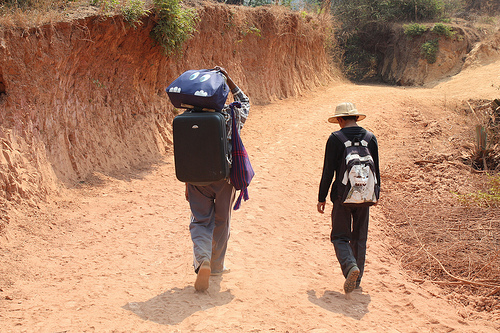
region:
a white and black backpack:
[335, 136, 378, 203]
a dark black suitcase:
[157, 108, 231, 188]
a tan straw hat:
[314, 98, 371, 124]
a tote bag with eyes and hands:
[162, 63, 237, 113]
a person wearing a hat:
[307, 98, 390, 298]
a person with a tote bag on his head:
[148, 56, 259, 299]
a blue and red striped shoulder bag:
[225, 101, 257, 212]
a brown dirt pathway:
[53, 212, 169, 317]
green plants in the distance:
[340, 11, 401, 76]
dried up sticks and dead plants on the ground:
[422, 208, 499, 284]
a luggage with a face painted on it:
[167, 68, 228, 110]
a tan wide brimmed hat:
[327, 101, 365, 122]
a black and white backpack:
[332, 130, 378, 204]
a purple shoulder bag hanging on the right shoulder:
[228, 105, 253, 210]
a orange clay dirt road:
[0, 6, 497, 331]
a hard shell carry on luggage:
[172, 111, 232, 183]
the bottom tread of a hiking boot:
[342, 266, 359, 292]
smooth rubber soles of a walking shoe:
[195, 261, 210, 292]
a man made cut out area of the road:
[1, 0, 330, 204]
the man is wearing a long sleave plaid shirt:
[222, 85, 249, 148]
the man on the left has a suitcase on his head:
[146, 45, 261, 115]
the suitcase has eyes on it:
[163, 53, 258, 128]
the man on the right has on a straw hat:
[298, 88, 363, 130]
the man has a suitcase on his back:
[171, 118, 238, 195]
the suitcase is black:
[171, 110, 243, 197]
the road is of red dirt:
[51, 207, 166, 319]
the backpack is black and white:
[333, 140, 388, 224]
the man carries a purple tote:
[231, 127, 263, 194]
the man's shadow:
[301, 269, 383, 316]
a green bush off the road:
[136, 2, 203, 49]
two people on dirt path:
[149, 56, 373, 298]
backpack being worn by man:
[335, 133, 380, 211]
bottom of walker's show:
[337, 260, 370, 294]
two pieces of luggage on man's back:
[164, 65, 235, 190]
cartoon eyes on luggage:
[182, 69, 216, 88]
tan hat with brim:
[326, 98, 375, 126]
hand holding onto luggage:
[201, 60, 233, 83]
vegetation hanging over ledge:
[150, 9, 193, 60]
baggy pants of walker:
[190, 190, 233, 256]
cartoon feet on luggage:
[166, 86, 213, 102]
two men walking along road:
[151, 56, 416, 304]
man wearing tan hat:
[313, 88, 410, 153]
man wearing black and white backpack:
[327, 118, 406, 243]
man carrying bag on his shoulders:
[157, 56, 248, 116]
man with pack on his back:
[158, 103, 251, 201]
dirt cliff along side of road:
[18, 7, 365, 119]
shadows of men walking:
[118, 265, 393, 322]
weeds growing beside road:
[443, 98, 499, 209]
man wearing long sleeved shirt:
[295, 118, 398, 217]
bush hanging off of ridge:
[116, 5, 263, 52]